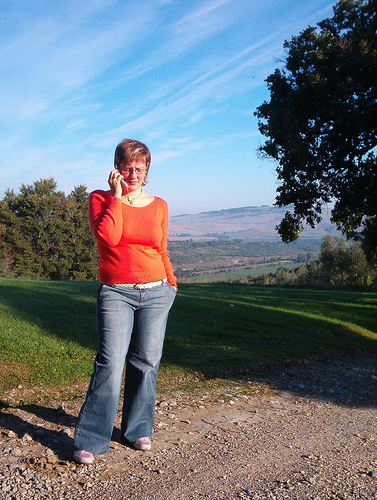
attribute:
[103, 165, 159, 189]
phone — cell phone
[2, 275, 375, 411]
grass — green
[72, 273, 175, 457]
jeans — blue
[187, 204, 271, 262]
hills — small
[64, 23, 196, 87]
sky — blue, clear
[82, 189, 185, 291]
shirt — orange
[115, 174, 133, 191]
cell phone — grey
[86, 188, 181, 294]
shirt — orange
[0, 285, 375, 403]
grass — green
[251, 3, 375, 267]
leaves — green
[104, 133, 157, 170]
hair — short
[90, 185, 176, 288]
sweater — long sleeved, red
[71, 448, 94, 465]
shoe — pink, white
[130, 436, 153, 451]
shoe — white, pink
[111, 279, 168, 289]
belt — white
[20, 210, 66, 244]
leaves — green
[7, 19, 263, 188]
clouds — thin